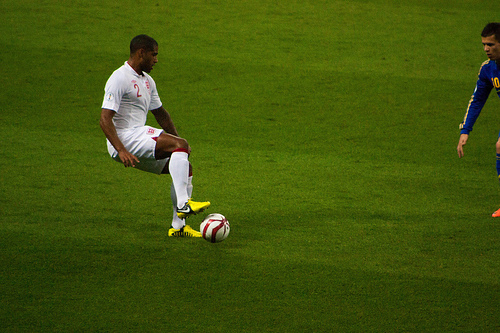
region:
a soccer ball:
[194, 212, 239, 244]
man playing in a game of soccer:
[87, 22, 238, 256]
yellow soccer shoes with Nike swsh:
[169, 193, 213, 217]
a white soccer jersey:
[95, 59, 173, 135]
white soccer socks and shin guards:
[159, 142, 196, 218]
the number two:
[122, 71, 144, 104]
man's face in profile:
[115, 28, 165, 79]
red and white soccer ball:
[196, 207, 234, 245]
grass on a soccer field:
[208, 56, 416, 178]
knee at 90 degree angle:
[163, 127, 194, 160]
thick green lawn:
[242, 9, 449, 308]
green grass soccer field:
[230, 10, 446, 331]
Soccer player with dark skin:
[77, 21, 254, 263]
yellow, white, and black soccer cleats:
[161, 196, 215, 242]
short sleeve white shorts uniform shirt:
[107, 60, 160, 140]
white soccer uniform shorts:
[98, 114, 168, 183]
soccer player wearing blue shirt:
[434, 12, 497, 237]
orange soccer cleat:
[480, 195, 499, 234]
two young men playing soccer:
[57, 7, 499, 253]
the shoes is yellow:
[140, 168, 287, 273]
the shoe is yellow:
[126, 160, 336, 311]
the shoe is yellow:
[158, 166, 224, 282]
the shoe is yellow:
[81, 110, 221, 233]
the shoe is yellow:
[160, 183, 213, 233]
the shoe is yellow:
[147, 147, 222, 237]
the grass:
[246, 147, 355, 308]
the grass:
[300, 94, 372, 290]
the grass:
[306, 174, 366, 301]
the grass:
[284, 163, 344, 311]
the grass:
[349, 116, 401, 306]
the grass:
[294, 71, 340, 258]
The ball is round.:
[193, 206, 239, 250]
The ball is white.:
[197, 201, 233, 251]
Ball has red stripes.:
[197, 205, 239, 253]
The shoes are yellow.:
[158, 192, 242, 244]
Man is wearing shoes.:
[105, 23, 245, 258]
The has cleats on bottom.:
[170, 195, 218, 221]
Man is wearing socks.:
[83, 17, 243, 261]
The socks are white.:
[93, 30, 232, 263]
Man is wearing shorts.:
[97, 23, 239, 253]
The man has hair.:
[86, 15, 238, 250]